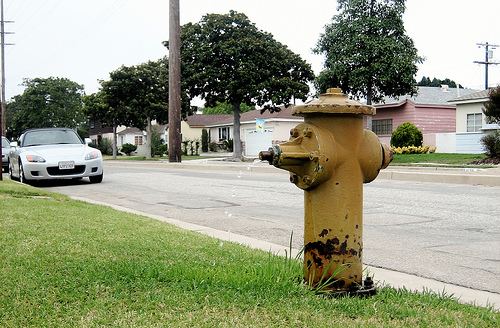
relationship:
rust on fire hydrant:
[306, 230, 358, 266] [259, 81, 396, 300]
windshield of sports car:
[23, 130, 81, 143] [3, 122, 108, 183]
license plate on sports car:
[54, 160, 79, 169] [3, 122, 108, 183]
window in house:
[457, 109, 484, 137] [443, 84, 499, 153]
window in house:
[369, 116, 394, 136] [365, 84, 454, 150]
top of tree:
[212, 10, 257, 28] [180, 8, 301, 162]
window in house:
[211, 127, 230, 141] [191, 108, 304, 152]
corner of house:
[452, 101, 462, 152] [443, 84, 499, 153]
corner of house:
[408, 106, 418, 130] [365, 84, 454, 150]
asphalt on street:
[163, 192, 253, 210] [81, 156, 499, 290]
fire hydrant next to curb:
[259, 81, 396, 300] [66, 194, 484, 320]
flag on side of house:
[252, 116, 265, 133] [365, 84, 454, 150]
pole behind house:
[161, 0, 187, 160] [365, 84, 454, 150]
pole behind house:
[472, 37, 499, 90] [365, 84, 454, 150]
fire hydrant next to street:
[259, 81, 396, 300] [81, 156, 499, 290]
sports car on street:
[3, 122, 108, 183] [81, 156, 499, 290]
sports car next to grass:
[3, 122, 108, 183] [3, 179, 294, 327]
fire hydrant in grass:
[259, 81, 396, 300] [3, 179, 294, 327]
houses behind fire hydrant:
[92, 79, 497, 155] [259, 81, 396, 300]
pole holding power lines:
[472, 37, 499, 90] [444, 38, 499, 59]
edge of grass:
[398, 158, 478, 163] [3, 179, 294, 327]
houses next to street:
[92, 79, 497, 155] [81, 156, 499, 290]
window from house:
[457, 109, 484, 137] [443, 84, 499, 153]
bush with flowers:
[389, 122, 421, 145] [390, 144, 439, 157]